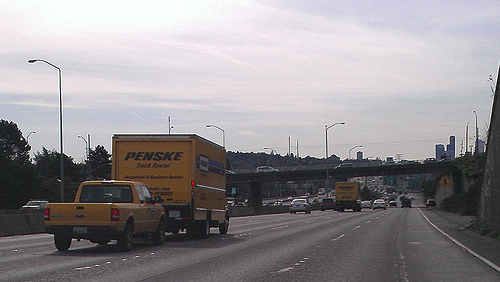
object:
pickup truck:
[39, 177, 170, 251]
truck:
[109, 132, 234, 239]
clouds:
[1, 0, 499, 128]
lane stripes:
[271, 207, 401, 278]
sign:
[438, 176, 451, 202]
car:
[254, 164, 280, 174]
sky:
[1, 8, 500, 164]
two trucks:
[40, 133, 234, 253]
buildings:
[430, 135, 458, 161]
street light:
[25, 58, 68, 202]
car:
[425, 196, 437, 207]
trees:
[82, 144, 113, 179]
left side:
[1, 4, 252, 281]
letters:
[170, 150, 185, 163]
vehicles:
[286, 196, 313, 215]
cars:
[332, 161, 353, 170]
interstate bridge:
[226, 158, 458, 205]